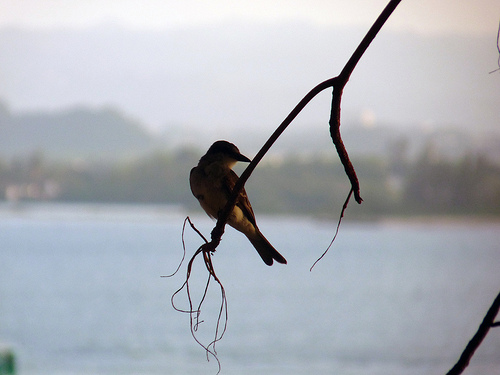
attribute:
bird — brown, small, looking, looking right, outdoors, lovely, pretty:
[190, 139, 288, 267]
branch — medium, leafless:
[159, 1, 402, 375]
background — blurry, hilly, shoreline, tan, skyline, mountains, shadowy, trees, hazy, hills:
[2, 0, 499, 374]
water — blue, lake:
[0, 202, 499, 375]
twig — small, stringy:
[161, 217, 209, 277]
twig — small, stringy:
[172, 244, 202, 315]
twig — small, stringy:
[193, 251, 212, 331]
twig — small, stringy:
[207, 291, 229, 363]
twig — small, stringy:
[186, 244, 221, 375]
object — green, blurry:
[0, 351, 15, 375]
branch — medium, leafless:
[445, 294, 500, 374]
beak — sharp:
[236, 153, 250, 163]